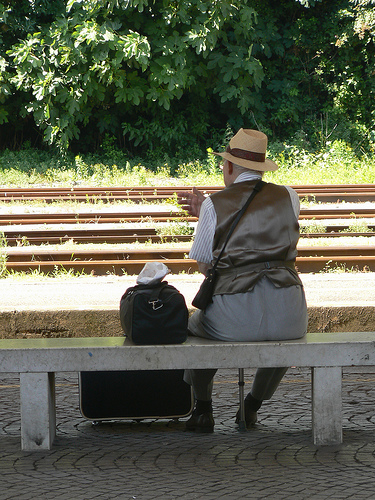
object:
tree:
[13, 4, 271, 142]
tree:
[271, 0, 373, 135]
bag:
[191, 268, 217, 311]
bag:
[120, 281, 189, 344]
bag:
[78, 370, 194, 422]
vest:
[207, 179, 304, 296]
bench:
[0, 332, 375, 450]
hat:
[211, 127, 278, 171]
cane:
[238, 368, 247, 432]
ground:
[0, 179, 372, 496]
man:
[176, 127, 307, 433]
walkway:
[0, 366, 373, 496]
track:
[0, 184, 375, 275]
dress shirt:
[188, 171, 299, 264]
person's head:
[224, 132, 266, 189]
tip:
[238, 422, 248, 432]